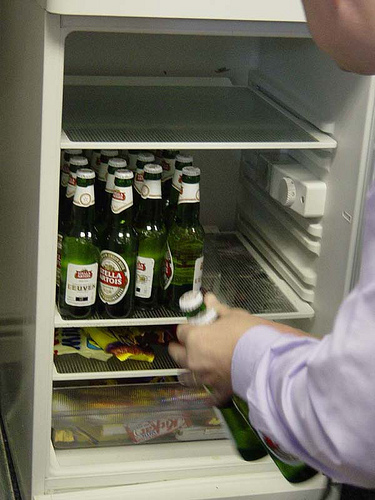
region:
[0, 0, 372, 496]
open refrigerator whose main contents is alcohol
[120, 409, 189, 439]
KitKat candy bar in the bottom drawer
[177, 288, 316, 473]
two bottles of alcoholic beverage in a man's hand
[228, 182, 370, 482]
long sleeved white dress shirt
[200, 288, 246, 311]
left thumb near the cap on the beverage bottle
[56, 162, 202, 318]
front row of four bottles of alcoholic beverages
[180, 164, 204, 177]
white cap on a green bottle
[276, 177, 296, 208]
round white temperature control dial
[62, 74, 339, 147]
completely empty top shelf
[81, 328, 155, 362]
bright yellow package on the shelf below the bottles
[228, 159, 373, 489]
Man wearing a shirt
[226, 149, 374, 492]
Man is wearing a shirt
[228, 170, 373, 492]
Man wearing a purple shirt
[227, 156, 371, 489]
Man is wearing a purple shirt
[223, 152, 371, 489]
Man wearing a lavender colored shirt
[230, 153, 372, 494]
Man is wearing a lavender colored shirt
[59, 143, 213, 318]
Bottles in the refrigerator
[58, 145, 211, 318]
Glass bottles in the refrigerator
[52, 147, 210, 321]
Bottles of beer in the refrigerator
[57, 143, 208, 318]
Glass bottles of beer in the refrigerator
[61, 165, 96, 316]
green bottle of beer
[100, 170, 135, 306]
green bottle of beer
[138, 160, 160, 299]
green bottle of beer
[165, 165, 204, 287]
green bottle of beer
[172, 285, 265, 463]
bottle of beer in man hand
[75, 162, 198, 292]
beer in a refrigerator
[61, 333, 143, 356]
food in a refrigerator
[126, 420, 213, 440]
food in a refrigerator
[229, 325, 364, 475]
man wearing a purple shirt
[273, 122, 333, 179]
shelf in a refrigerator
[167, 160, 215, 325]
this is a bottle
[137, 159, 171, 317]
this is a bottle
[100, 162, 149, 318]
this is a bottle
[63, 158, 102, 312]
this is a bottle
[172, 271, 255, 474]
this is a bottle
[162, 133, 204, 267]
this is a bottle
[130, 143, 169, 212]
this is a bottle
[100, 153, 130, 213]
this is a bottle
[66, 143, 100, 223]
this is a bottle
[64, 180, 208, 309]
several bottles of tequila shots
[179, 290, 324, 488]
person holding bottles of tequila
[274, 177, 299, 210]
dial on the inside of the fridge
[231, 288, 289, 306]
shelf in the fridge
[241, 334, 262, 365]
cufflink on the shirt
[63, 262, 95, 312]
label on the bottle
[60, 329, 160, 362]
food on the shelf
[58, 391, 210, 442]
food in the bin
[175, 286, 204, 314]
cap on the bottle